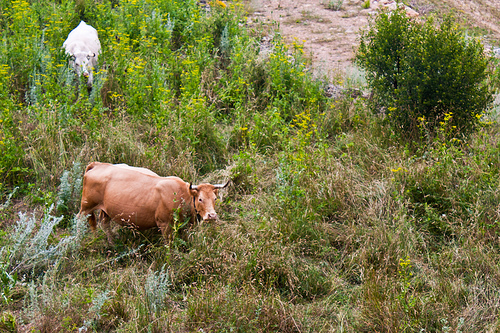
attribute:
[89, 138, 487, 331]
grass — brown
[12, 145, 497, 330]
grass — green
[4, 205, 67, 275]
plants — wild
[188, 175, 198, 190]
horn — sharp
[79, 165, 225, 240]
cow — white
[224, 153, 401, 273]
grass — green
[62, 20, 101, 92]
cow — white